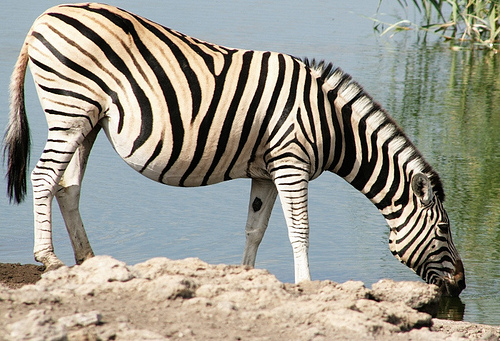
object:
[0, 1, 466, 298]
zebra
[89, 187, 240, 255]
water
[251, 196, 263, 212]
spot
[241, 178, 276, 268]
leg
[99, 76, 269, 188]
belly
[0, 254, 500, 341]
ground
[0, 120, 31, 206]
hair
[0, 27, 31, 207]
tail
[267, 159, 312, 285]
leg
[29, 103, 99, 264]
leg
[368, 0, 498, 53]
plants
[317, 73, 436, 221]
neck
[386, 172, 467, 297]
head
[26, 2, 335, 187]
body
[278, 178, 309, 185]
stripes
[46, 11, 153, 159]
stripe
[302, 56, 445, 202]
mane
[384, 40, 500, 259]
reflection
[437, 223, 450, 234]
eye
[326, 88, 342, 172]
stripe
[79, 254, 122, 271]
edge